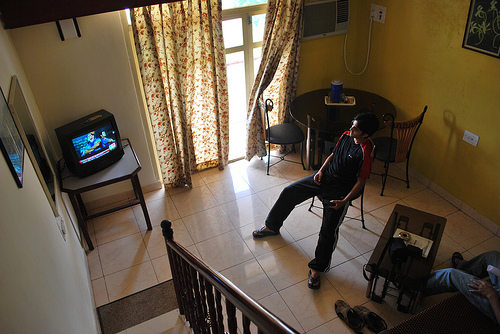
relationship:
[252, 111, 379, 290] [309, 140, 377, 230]
man sitting in chair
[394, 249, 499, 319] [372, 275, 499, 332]
man sitting on couch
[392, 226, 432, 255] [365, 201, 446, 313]
magazine on top of coffee table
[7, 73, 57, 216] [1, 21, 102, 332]
picture hanging on wall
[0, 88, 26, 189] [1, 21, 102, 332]
picture hanging on wall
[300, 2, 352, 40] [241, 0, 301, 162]
air conditioner next to curtains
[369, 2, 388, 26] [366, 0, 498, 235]
electrical outlet attached to walls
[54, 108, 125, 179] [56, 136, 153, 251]
television sitting on table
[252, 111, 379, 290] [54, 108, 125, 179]
man watching television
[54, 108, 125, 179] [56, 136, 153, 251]
television set on table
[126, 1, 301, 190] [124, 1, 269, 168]
curtains hung over window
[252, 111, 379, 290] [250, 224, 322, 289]
man wearing flip flops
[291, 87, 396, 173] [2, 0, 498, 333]
table in corner of room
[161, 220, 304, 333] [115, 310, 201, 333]
banaster next to stairs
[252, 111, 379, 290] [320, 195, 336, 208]
man holding remote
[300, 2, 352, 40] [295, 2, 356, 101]
air conditioner mounted on wall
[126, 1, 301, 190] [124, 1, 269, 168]
curtains hanging over window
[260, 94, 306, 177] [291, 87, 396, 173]
chair next to table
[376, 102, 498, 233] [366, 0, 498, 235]
shadow cast on walls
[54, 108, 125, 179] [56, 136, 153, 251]
television on top of table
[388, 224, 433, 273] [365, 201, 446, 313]
stuff on top of coffee table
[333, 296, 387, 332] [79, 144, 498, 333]
shoes sitting on floor